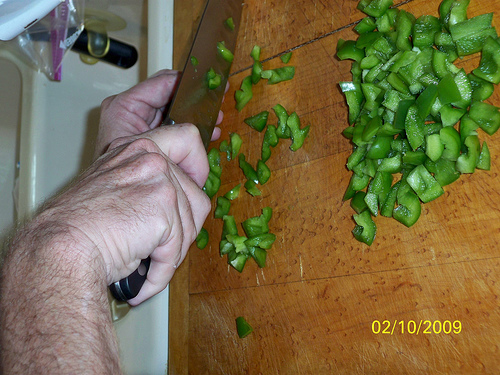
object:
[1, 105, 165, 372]
forearms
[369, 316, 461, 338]
date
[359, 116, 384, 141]
peppers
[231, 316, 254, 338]
peppers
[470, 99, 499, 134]
pepper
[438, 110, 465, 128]
pepper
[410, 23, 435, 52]
pepper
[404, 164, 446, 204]
pepper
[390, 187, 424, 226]
pepper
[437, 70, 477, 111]
pepper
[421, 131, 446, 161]
pepper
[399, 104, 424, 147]
pepper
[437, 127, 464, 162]
pepper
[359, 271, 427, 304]
marks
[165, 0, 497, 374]
board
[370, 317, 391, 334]
02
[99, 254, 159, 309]
handle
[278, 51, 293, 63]
peppers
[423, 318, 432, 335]
2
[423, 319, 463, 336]
2009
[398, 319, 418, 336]
10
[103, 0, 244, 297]
knife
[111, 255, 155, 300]
end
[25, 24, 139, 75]
object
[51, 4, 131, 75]
holder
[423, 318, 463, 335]
year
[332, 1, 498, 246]
green pepper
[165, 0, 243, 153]
blade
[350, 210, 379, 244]
peppers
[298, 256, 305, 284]
scratches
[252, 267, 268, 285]
scratches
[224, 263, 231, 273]
scratches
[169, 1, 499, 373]
table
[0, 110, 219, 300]
hand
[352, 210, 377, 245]
pepper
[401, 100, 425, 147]
pepper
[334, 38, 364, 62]
pepper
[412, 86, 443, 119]
pepper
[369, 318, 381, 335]
number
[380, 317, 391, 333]
number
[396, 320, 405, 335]
number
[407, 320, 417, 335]
number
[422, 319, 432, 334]
number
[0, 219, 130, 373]
arm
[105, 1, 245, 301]
knife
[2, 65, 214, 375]
male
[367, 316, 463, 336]
print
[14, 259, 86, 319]
hair